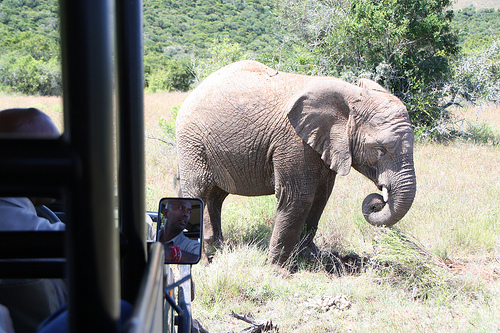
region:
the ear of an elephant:
[283, 82, 360, 176]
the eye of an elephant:
[367, 139, 394, 159]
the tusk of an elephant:
[375, 177, 395, 207]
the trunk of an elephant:
[356, 157, 423, 227]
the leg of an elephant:
[262, 177, 322, 269]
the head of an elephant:
[347, 78, 422, 186]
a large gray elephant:
[167, 55, 429, 278]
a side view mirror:
[153, 189, 211, 271]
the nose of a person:
[179, 204, 191, 219]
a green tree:
[309, 0, 472, 142]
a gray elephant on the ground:
[166, 55, 421, 279]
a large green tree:
[300, 0, 465, 143]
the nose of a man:
[178, 205, 192, 222]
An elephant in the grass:
[184, 54, 413, 278]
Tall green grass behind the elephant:
[422, 143, 485, 247]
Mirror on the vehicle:
[160, 198, 205, 265]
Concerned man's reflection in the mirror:
[162, 201, 199, 256]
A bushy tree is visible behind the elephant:
[339, 0, 449, 98]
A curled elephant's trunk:
[364, 183, 412, 233]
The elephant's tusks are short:
[375, 184, 395, 205]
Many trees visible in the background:
[149, 11, 293, 58]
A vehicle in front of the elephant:
[2, 1, 154, 315]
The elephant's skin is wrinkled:
[204, 73, 310, 182]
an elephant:
[199, 90, 349, 286]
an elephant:
[202, 52, 329, 209]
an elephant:
[214, 90, 301, 165]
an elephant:
[165, 25, 286, 327]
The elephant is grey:
[170, 46, 427, 268]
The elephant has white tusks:
[335, 86, 435, 239]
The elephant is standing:
[168, 40, 400, 264]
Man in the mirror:
[144, 179, 231, 286]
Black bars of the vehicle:
[25, 5, 175, 318]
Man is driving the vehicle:
[5, 105, 215, 261]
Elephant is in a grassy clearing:
[163, 35, 429, 256]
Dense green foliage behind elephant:
[68, 0, 475, 141]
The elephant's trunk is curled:
[289, 63, 436, 240]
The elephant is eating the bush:
[196, 48, 453, 295]